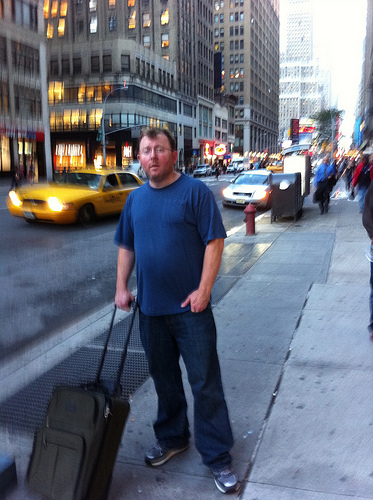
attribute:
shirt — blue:
[315, 162, 335, 185]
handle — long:
[95, 291, 140, 394]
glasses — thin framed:
[136, 146, 171, 155]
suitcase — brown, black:
[23, 372, 130, 499]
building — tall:
[212, 0, 276, 159]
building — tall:
[275, 0, 335, 145]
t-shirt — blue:
[112, 169, 229, 316]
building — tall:
[44, 0, 218, 181]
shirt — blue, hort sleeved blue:
[111, 174, 225, 315]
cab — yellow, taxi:
[5, 163, 154, 232]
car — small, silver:
[222, 164, 277, 211]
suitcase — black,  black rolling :
[22, 290, 137, 496]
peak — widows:
[145, 129, 167, 139]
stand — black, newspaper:
[268, 170, 303, 222]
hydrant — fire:
[242, 200, 258, 237]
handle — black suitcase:
[66, 291, 156, 401]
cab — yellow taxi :
[7, 165, 142, 238]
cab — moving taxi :
[5, 160, 144, 242]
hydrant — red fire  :
[241, 200, 262, 242]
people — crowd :
[310, 148, 360, 208]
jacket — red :
[348, 150, 359, 187]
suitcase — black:
[24, 292, 147, 487]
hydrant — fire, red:
[242, 204, 260, 239]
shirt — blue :
[312, 163, 336, 192]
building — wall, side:
[215, 2, 242, 153]